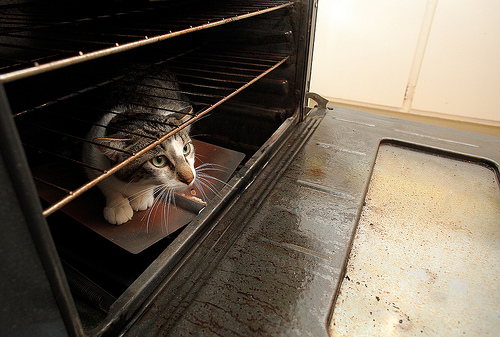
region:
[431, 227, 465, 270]
part of a glassy part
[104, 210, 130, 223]
part of the right paw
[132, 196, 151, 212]
part of the left paw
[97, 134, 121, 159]
part of the right ear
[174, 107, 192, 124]
part of the left ear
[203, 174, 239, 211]
part of some whiskers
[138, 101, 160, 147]
head of a cat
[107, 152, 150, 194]
right jaw of a cat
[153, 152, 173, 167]
right eye of a cat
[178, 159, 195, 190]
nose of a cat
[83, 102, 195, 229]
Kitty in the oven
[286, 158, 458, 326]
Greasy oven door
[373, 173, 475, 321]
Oven window splattered with grease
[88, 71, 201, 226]
Cat hiding in turned off oven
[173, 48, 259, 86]
Rack in the middle of the oven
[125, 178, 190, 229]
Long white kitty whiskers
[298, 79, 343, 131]
Hinge on opened oven door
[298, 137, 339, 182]
Brown grease splatter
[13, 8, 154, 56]
Empty upper oven rack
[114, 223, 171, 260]
Metal plate inside oven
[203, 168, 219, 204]
part of some whiskers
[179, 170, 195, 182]
nose of a cat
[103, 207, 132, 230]
right paw of a cat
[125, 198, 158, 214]
left paw of a cat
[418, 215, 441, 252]
part of a glassy part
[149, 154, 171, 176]
right eye of a cat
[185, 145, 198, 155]
left eye of a cat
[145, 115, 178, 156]
head of a cat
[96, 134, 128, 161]
right ear of a cat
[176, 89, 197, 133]
left ear of a cat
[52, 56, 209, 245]
Black and white cat with stripes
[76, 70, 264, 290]
Cat is in oven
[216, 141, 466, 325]
Oven door needs to be cleaned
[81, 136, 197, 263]
Cat has white paws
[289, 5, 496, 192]
Wall behind oven is white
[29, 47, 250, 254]
Cat under wire screen in oven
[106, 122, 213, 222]
Cats eyes are yellow green color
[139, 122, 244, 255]
Cat's whiskers are white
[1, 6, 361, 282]
Oven has 3 wire racks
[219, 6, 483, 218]
Oven door is wide open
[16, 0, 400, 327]
the cat is in the oven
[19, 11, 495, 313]
the oven door is open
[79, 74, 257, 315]
the cat is looking outside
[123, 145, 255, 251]
the cat has whiskers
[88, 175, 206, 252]
cat's paws are white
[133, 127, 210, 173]
cat's eyes are green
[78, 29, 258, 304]
the oven grills are rusty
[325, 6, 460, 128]
the wall is white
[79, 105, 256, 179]
the cat has two ears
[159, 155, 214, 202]
the nose is brown